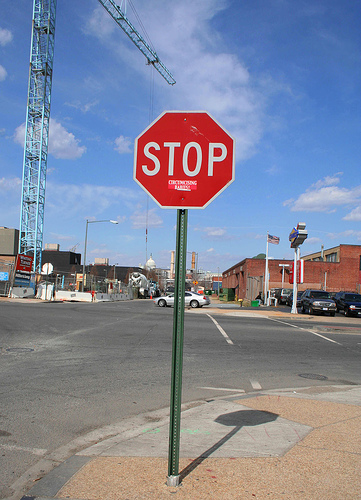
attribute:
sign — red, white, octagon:
[133, 110, 236, 210]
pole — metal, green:
[166, 208, 187, 487]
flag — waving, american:
[268, 234, 281, 245]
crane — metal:
[17, 2, 175, 283]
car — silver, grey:
[153, 291, 209, 309]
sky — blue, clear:
[1, 2, 358, 274]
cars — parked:
[263, 287, 360, 317]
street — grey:
[2, 294, 360, 499]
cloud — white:
[14, 117, 85, 162]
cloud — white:
[279, 176, 359, 225]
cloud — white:
[82, 1, 294, 167]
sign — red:
[15, 254, 36, 273]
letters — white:
[141, 141, 225, 178]